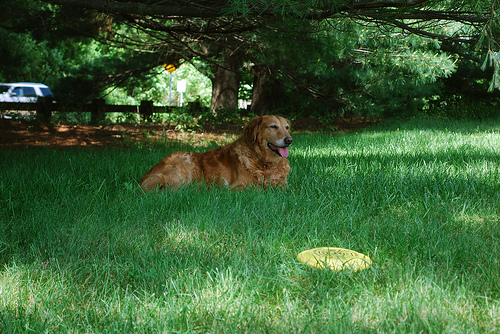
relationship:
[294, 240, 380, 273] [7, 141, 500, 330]
frisbee in grass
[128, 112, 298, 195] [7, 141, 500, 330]
dog in grass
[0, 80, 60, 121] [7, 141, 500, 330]
car behind grass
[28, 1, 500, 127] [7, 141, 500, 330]
trees behind grass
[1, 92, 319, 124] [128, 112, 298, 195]
fence behind dog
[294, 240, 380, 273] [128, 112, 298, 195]
frisbee near dog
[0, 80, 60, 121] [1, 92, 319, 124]
car near fence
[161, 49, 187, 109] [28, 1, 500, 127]
sign behind trees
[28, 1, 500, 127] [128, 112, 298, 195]
trees behind dog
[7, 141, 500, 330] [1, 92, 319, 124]
grass in front of fence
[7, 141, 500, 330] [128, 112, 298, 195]
grass around dog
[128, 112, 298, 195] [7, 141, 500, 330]
dog laying in grass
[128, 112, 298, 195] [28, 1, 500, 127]
dog under trees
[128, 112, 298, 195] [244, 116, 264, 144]
dog has ears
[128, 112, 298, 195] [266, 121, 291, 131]
dog has eyes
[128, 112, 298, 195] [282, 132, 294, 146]
dog has nose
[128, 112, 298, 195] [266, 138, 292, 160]
dog has mouth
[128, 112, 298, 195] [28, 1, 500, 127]
dog laying under trees